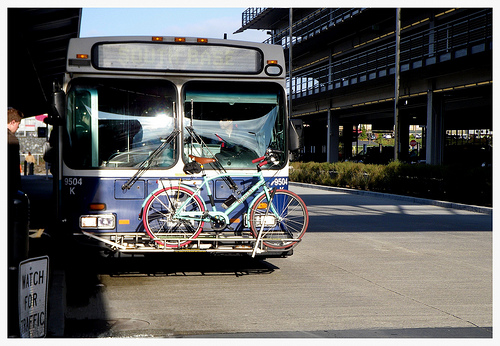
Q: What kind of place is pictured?
A: It is a street.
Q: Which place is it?
A: It is a street.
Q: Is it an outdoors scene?
A: Yes, it is outdoors.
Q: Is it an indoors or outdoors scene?
A: It is outdoors.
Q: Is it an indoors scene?
A: No, it is outdoors.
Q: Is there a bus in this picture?
A: Yes, there is a bus.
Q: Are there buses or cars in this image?
A: Yes, there is a bus.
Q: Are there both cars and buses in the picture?
A: No, there is a bus but no cars.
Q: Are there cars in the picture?
A: No, there are no cars.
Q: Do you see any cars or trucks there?
A: No, there are no cars or trucks.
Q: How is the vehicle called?
A: The vehicle is a bus.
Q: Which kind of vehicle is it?
A: The vehicle is a bus.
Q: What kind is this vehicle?
A: This is a bus.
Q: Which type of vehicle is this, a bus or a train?
A: This is a bus.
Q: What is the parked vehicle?
A: The vehicle is a bus.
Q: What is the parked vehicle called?
A: The vehicle is a bus.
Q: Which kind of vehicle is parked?
A: The vehicle is a bus.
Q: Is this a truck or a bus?
A: This is a bus.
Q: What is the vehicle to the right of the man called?
A: The vehicle is a bus.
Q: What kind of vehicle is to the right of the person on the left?
A: The vehicle is a bus.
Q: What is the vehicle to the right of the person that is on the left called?
A: The vehicle is a bus.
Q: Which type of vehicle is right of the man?
A: The vehicle is a bus.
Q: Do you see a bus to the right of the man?
A: Yes, there is a bus to the right of the man.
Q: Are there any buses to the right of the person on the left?
A: Yes, there is a bus to the right of the man.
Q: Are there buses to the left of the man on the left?
A: No, the bus is to the right of the man.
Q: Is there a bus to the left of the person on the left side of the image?
A: No, the bus is to the right of the man.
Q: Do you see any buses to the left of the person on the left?
A: No, the bus is to the right of the man.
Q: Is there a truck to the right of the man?
A: No, there is a bus to the right of the man.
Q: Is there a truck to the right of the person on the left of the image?
A: No, there is a bus to the right of the man.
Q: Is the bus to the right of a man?
A: Yes, the bus is to the right of a man.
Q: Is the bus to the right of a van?
A: No, the bus is to the right of a man.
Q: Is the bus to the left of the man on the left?
A: No, the bus is to the right of the man.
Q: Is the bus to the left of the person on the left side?
A: No, the bus is to the right of the man.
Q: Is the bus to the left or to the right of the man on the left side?
A: The bus is to the right of the man.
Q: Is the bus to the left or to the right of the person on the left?
A: The bus is to the right of the man.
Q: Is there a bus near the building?
A: Yes, there is a bus near the building.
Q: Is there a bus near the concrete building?
A: Yes, there is a bus near the building.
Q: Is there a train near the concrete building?
A: No, there is a bus near the building.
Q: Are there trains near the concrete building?
A: No, there is a bus near the building.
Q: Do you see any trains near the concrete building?
A: No, there is a bus near the building.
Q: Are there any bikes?
A: Yes, there is a bike.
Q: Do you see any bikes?
A: Yes, there is a bike.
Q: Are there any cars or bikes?
A: Yes, there is a bike.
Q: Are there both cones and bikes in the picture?
A: No, there is a bike but no cones.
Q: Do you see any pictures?
A: No, there are no pictures.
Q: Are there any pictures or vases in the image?
A: No, there are no pictures or vases.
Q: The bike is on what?
A: The bike is on the bus.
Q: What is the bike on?
A: The bike is on the bus.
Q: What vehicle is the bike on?
A: The bike is on the bus.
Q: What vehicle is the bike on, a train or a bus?
A: The bike is on a bus.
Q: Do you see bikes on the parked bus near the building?
A: Yes, there is a bike on the bus.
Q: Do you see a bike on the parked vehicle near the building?
A: Yes, there is a bike on the bus.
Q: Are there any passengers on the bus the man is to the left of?
A: No, there is a bike on the bus.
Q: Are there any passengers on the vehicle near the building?
A: No, there is a bike on the bus.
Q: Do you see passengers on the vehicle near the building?
A: No, there is a bike on the bus.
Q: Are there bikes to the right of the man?
A: Yes, there is a bike to the right of the man.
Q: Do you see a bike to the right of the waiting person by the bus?
A: Yes, there is a bike to the right of the man.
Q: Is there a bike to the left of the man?
A: No, the bike is to the right of the man.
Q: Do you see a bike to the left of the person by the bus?
A: No, the bike is to the right of the man.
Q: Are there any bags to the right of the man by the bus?
A: No, there is a bike to the right of the man.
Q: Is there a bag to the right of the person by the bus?
A: No, there is a bike to the right of the man.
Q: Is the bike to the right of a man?
A: Yes, the bike is to the right of a man.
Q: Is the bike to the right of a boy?
A: No, the bike is to the right of a man.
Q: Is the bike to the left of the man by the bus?
A: No, the bike is to the right of the man.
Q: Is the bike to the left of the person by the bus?
A: No, the bike is to the right of the man.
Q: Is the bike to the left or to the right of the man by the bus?
A: The bike is to the right of the man.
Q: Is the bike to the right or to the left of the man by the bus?
A: The bike is to the right of the man.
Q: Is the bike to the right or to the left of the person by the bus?
A: The bike is to the right of the man.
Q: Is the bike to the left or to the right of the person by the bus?
A: The bike is to the right of the man.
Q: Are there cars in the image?
A: No, there are no cars.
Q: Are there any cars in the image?
A: No, there are no cars.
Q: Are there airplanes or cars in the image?
A: No, there are no cars or airplanes.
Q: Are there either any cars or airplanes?
A: No, there are no cars or airplanes.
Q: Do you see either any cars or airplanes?
A: No, there are no cars or airplanes.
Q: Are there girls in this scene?
A: No, there are no girls.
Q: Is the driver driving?
A: Yes, the driver is driving.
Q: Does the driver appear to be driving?
A: Yes, the driver is driving.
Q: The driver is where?
A: The driver is in the bus.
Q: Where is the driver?
A: The driver is in the bus.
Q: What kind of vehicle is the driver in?
A: The driver is in the bus.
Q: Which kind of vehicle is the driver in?
A: The driver is in the bus.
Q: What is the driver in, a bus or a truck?
A: The driver is in a bus.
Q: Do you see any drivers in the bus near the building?
A: Yes, there is a driver in the bus.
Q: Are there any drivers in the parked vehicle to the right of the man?
A: Yes, there is a driver in the bus.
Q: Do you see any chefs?
A: No, there are no chefs.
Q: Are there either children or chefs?
A: No, there are no chefs or children.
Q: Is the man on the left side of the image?
A: Yes, the man is on the left of the image.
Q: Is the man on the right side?
A: No, the man is on the left of the image.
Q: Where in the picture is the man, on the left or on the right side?
A: The man is on the left of the image.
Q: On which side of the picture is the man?
A: The man is on the left of the image.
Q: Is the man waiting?
A: Yes, the man is waiting.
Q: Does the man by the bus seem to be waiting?
A: Yes, the man is waiting.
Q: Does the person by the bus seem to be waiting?
A: Yes, the man is waiting.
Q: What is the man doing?
A: The man is waiting.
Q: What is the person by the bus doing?
A: The man is waiting.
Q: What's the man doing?
A: The man is waiting.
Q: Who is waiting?
A: The man is waiting.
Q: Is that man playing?
A: No, the man is waiting.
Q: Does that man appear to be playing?
A: No, the man is waiting.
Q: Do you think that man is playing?
A: No, the man is waiting.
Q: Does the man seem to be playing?
A: No, the man is waiting.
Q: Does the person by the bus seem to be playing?
A: No, the man is waiting.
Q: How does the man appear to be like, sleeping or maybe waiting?
A: The man is waiting.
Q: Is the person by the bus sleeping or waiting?
A: The man is waiting.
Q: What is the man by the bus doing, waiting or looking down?
A: The man is waiting.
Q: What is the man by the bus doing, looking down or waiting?
A: The man is waiting.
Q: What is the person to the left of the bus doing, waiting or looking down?
A: The man is waiting.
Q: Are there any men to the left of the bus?
A: Yes, there is a man to the left of the bus.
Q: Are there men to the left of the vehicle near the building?
A: Yes, there is a man to the left of the bus.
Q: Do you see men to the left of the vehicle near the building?
A: Yes, there is a man to the left of the bus.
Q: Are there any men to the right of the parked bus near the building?
A: No, the man is to the left of the bus.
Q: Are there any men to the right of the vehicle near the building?
A: No, the man is to the left of the bus.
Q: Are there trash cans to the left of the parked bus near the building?
A: No, there is a man to the left of the bus.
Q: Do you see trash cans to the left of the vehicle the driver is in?
A: No, there is a man to the left of the bus.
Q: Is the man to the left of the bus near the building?
A: Yes, the man is to the left of the bus.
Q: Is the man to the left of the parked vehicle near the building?
A: Yes, the man is to the left of the bus.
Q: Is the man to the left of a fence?
A: No, the man is to the left of the bus.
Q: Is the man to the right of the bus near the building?
A: No, the man is to the left of the bus.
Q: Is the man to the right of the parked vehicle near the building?
A: No, the man is to the left of the bus.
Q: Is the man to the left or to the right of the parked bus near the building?
A: The man is to the left of the bus.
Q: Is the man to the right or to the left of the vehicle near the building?
A: The man is to the left of the bus.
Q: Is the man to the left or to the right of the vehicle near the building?
A: The man is to the left of the bus.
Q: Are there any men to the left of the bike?
A: Yes, there is a man to the left of the bike.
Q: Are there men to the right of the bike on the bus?
A: No, the man is to the left of the bike.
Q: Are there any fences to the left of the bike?
A: No, there is a man to the left of the bike.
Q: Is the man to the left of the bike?
A: Yes, the man is to the left of the bike.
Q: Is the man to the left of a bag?
A: No, the man is to the left of the bike.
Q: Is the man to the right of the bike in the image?
A: No, the man is to the left of the bike.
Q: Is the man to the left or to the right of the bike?
A: The man is to the left of the bike.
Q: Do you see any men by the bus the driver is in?
A: Yes, there is a man by the bus.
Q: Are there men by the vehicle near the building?
A: Yes, there is a man by the bus.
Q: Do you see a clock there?
A: No, there are no clocks.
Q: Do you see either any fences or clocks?
A: No, there are no clocks or fences.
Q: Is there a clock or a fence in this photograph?
A: No, there are no clocks or fences.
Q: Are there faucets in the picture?
A: No, there are no faucets.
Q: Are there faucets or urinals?
A: No, there are no faucets or urinals.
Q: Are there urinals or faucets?
A: No, there are no faucets or urinals.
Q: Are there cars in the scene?
A: No, there are no cars.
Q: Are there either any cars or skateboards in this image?
A: No, there are no cars or skateboards.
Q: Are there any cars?
A: No, there are no cars.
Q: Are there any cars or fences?
A: No, there are no cars or fences.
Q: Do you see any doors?
A: Yes, there is a door.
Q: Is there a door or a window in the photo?
A: Yes, there is a door.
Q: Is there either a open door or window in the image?
A: Yes, there is an open door.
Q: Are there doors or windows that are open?
A: Yes, the door is open.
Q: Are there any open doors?
A: Yes, there is an open door.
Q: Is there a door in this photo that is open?
A: Yes, there is a door that is open.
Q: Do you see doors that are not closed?
A: Yes, there is a open door.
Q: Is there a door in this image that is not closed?
A: Yes, there is a open door.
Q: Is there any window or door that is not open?
A: No, there is a door but it is open.